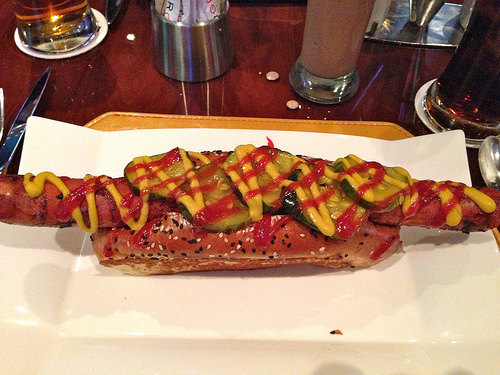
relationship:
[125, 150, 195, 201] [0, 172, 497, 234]
pickle on hot dog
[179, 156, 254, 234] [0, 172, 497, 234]
pickle on hot dog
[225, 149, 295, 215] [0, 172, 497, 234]
pickle on hot dog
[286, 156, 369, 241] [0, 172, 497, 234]
pickle on hot dog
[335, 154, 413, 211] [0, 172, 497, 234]
pickle on hot dog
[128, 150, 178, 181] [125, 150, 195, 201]
ketchup on pickle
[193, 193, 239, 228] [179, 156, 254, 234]
ketchup on pickle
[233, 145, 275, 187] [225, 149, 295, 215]
ketchup on pickle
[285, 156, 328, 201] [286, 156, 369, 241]
ketchup on pickle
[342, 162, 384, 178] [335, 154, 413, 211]
ketchup on pickle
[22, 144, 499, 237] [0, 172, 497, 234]
mustard on hot dog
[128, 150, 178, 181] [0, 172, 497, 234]
ketchup on hot dog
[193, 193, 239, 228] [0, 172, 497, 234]
ketchup on hot dog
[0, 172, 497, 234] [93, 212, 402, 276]
hot dog on bun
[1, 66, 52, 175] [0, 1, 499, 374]
knife on table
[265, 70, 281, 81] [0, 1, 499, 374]
pill on table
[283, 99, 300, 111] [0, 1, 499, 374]
pill on table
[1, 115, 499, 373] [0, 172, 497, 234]
plate under hot dog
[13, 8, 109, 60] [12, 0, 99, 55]
coaster under drink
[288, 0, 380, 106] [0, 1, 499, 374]
glass on table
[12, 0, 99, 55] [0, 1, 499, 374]
drink on table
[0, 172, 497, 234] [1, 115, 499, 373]
hot dog on plate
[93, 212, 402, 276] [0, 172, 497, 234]
bun under hot dog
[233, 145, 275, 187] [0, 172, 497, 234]
ketchup on hot dog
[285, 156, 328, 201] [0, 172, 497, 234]
ketchup on hot dog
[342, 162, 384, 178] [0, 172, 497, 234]
ketchup on hot dog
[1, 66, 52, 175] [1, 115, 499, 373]
knife next to plate